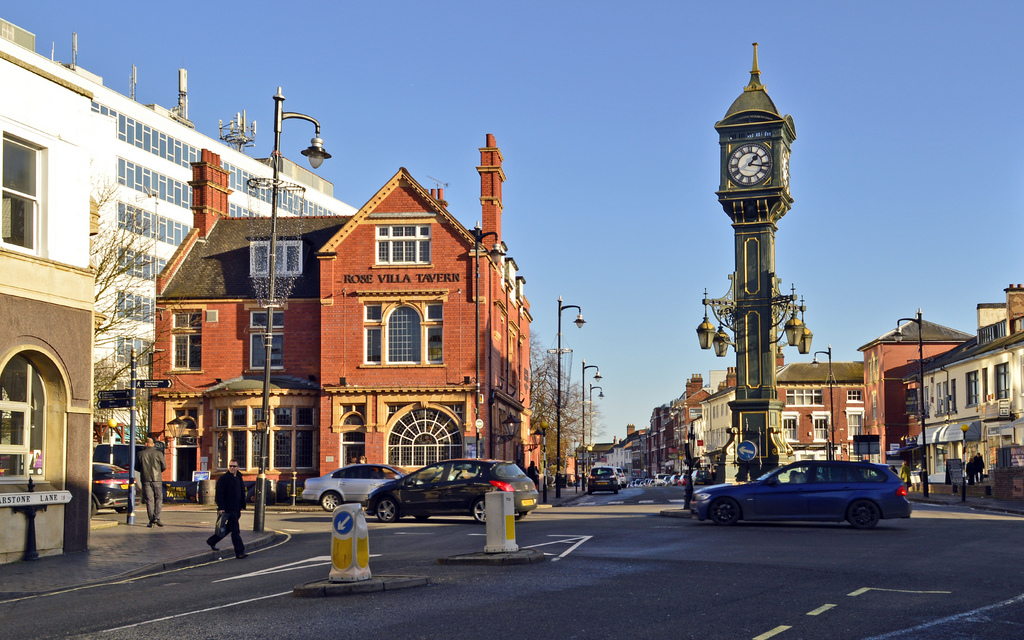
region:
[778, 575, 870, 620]
lines that are white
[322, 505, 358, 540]
a sign that is blue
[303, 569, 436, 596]
a curb that is grey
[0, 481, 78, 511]
a sign that is white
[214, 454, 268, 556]
a man that is walking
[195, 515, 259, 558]
the legs of a man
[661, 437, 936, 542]
THE CAR IS BLUE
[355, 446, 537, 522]
THE CAR IS BLACK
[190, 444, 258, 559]
THE MAN IS WALKING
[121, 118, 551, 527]
THE BUILDING IS MADE OF RED BRICK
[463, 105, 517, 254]
THE CHIMNEY IS ON THE ROOF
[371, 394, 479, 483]
THE WINDOW IS ARCHED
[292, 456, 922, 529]
THE CARS ARE ON THE STREET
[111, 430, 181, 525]
THE MAN IS LEANING ON THE POST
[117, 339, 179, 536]
THE STREET SIGN IS BLUE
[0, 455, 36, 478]
window on the building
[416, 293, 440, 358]
window on the building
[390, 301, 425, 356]
window on the building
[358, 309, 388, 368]
window on the building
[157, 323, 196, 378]
window on the building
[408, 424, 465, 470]
window on the building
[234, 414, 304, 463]
window on the building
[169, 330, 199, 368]
glass window on the building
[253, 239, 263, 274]
glass window on the building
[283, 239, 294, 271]
glass window on the building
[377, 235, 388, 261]
glass window on the building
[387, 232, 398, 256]
glass window on the building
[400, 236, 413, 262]
glass window on the building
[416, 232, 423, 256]
glass window on the building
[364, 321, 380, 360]
glass window on the building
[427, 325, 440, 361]
glass window on the building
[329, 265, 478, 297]
Rose Villa Tavern sign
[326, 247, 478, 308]
Rose Villa Tavern sign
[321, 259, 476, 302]
Rose Villa Tavern sign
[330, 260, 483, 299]
Rose Villa Tavern sign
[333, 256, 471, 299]
Rose Villa Tavern sign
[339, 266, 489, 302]
Rose Villa Tavern sign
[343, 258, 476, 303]
Rose Villa Tavern sign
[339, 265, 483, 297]
Rose Villa Tavern sign